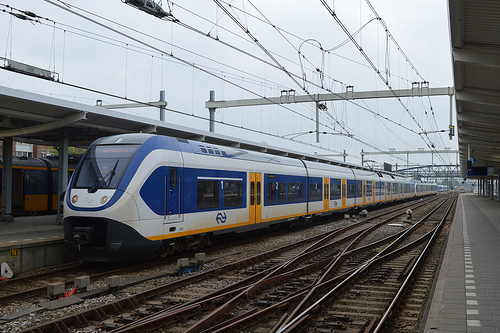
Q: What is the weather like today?
A: It is overcast.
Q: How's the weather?
A: It is overcast.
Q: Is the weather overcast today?
A: Yes, it is overcast.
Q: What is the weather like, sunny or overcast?
A: It is overcast.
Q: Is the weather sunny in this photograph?
A: No, it is overcast.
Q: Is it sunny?
A: No, it is overcast.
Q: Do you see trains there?
A: Yes, there is a train.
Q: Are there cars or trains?
A: Yes, there is a train.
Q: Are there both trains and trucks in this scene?
A: No, there is a train but no trucks.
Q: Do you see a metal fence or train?
A: Yes, there is a metal train.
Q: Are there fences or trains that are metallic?
A: Yes, the train is metallic.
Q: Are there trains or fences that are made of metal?
A: Yes, the train is made of metal.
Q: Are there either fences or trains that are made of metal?
A: Yes, the train is made of metal.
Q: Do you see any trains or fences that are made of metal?
A: Yes, the train is made of metal.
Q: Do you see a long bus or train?
A: Yes, there is a long train.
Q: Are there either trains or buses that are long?
A: Yes, the train is long.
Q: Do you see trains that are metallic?
A: Yes, there is a metal train.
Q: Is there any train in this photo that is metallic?
A: Yes, there is a train that is metallic.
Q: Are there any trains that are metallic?
A: Yes, there is a train that is metallic.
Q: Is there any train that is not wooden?
A: Yes, there is a metallic train.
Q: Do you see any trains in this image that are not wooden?
A: Yes, there is a metallic train.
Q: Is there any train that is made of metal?
A: Yes, there is a train that is made of metal.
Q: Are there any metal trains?
A: Yes, there is a train that is made of metal.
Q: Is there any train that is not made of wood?
A: Yes, there is a train that is made of metal.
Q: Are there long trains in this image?
A: Yes, there is a long train.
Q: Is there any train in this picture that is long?
A: Yes, there is a long train.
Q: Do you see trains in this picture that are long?
A: Yes, there is a train that is long.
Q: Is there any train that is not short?
A: Yes, there is a long train.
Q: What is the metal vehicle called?
A: The vehicle is a train.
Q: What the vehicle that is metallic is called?
A: The vehicle is a train.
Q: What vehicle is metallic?
A: The vehicle is a train.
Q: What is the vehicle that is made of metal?
A: The vehicle is a train.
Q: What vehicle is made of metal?
A: The vehicle is a train.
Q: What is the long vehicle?
A: The vehicle is a train.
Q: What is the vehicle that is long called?
A: The vehicle is a train.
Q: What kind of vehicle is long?
A: The vehicle is a train.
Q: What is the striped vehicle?
A: The vehicle is a train.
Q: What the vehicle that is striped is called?
A: The vehicle is a train.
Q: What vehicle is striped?
A: The vehicle is a train.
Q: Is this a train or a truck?
A: This is a train.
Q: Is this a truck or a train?
A: This is a train.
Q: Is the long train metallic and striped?
A: Yes, the train is metallic and striped.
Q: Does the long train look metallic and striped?
A: Yes, the train is metallic and striped.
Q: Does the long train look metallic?
A: Yes, the train is metallic.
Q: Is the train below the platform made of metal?
A: Yes, the train is made of metal.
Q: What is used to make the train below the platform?
A: The train is made of metal.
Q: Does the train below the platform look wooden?
A: No, the train is metallic.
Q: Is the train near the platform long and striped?
A: Yes, the train is long and striped.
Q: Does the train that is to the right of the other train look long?
A: Yes, the train is long.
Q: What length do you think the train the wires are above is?
A: The train is long.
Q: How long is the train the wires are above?
A: The train is long.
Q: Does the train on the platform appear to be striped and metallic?
A: Yes, the train is striped and metallic.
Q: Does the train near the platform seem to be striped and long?
A: Yes, the train is striped and long.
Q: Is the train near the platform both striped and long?
A: Yes, the train is striped and long.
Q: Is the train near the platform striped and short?
A: No, the train is striped but long.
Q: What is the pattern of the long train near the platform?
A: The train is striped.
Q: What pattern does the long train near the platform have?
A: The train has striped pattern.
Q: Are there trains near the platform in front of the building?
A: Yes, there is a train near the platform.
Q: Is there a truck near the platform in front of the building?
A: No, there is a train near the platform.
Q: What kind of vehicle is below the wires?
A: The vehicle is a train.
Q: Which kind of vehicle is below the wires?
A: The vehicle is a train.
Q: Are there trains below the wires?
A: Yes, there is a train below the wires.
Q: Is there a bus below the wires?
A: No, there is a train below the wires.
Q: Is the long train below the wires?
A: Yes, the train is below the wires.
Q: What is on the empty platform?
A: The train is on the platform.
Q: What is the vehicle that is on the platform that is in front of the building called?
A: The vehicle is a train.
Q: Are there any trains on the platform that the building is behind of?
A: Yes, there is a train on the platform.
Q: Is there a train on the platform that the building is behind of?
A: Yes, there is a train on the platform.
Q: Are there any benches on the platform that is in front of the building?
A: No, there is a train on the platform.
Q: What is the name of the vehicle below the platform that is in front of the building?
A: The vehicle is a train.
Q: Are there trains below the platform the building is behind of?
A: Yes, there is a train below the platform.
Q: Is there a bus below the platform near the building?
A: No, there is a train below the platform.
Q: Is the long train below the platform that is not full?
A: Yes, the train is below the platform.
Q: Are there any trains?
A: Yes, there is a train.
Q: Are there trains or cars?
A: Yes, there is a train.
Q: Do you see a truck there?
A: No, there are no trucks.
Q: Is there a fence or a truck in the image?
A: No, there are no trucks or fences.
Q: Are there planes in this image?
A: No, there are no planes.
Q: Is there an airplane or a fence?
A: No, there are no airplanes or fences.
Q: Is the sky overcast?
A: Yes, the sky is overcast.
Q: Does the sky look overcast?
A: Yes, the sky is overcast.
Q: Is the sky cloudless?
A: No, the sky is overcast.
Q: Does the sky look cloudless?
A: No, the sky is overcast.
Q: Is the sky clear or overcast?
A: The sky is overcast.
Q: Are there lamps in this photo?
A: No, there are no lamps.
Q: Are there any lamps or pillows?
A: No, there are no lamps or pillows.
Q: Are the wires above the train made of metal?
A: Yes, the wires are above the train.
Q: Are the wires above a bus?
A: No, the wires are above the train.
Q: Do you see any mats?
A: No, there are no mats.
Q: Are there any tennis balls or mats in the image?
A: No, there are no mats or tennis balls.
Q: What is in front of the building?
A: The platform is in front of the building.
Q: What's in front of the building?
A: The platform is in front of the building.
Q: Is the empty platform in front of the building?
A: Yes, the platform is in front of the building.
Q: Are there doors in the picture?
A: Yes, there is a door.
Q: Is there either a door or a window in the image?
A: Yes, there is a door.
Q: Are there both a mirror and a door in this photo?
A: No, there is a door but no mirrors.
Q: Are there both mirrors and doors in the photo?
A: No, there is a door but no mirrors.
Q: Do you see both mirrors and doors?
A: No, there is a door but no mirrors.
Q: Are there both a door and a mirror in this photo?
A: No, there is a door but no mirrors.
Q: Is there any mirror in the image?
A: No, there are no mirrors.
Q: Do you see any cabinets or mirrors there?
A: No, there are no mirrors or cabinets.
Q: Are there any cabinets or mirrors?
A: No, there are no mirrors or cabinets.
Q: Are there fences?
A: No, there are no fences.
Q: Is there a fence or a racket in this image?
A: No, there are no fences or rackets.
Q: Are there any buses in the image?
A: No, there are no buses.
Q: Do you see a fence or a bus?
A: No, there are no buses or fences.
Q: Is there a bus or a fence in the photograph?
A: No, there are no buses or fences.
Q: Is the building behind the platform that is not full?
A: Yes, the building is behind the platform.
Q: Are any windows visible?
A: Yes, there are windows.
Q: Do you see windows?
A: Yes, there are windows.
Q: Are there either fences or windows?
A: Yes, there are windows.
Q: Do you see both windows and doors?
A: Yes, there are both windows and doors.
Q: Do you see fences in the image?
A: No, there are no fences.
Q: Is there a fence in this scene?
A: No, there are no fences.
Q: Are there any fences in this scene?
A: No, there are no fences.